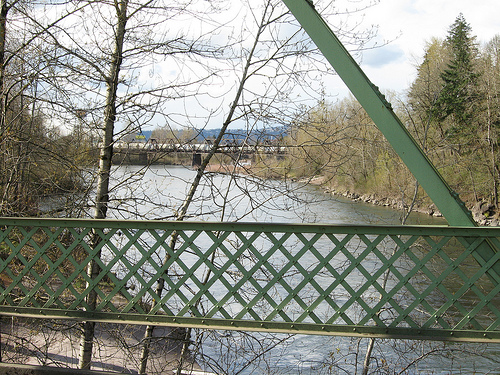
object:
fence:
[0, 214, 499, 343]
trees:
[111, 0, 327, 374]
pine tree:
[404, 13, 499, 214]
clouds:
[347, 36, 408, 71]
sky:
[0, 0, 499, 143]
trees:
[0, 0, 251, 373]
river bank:
[0, 306, 202, 375]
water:
[60, 164, 500, 374]